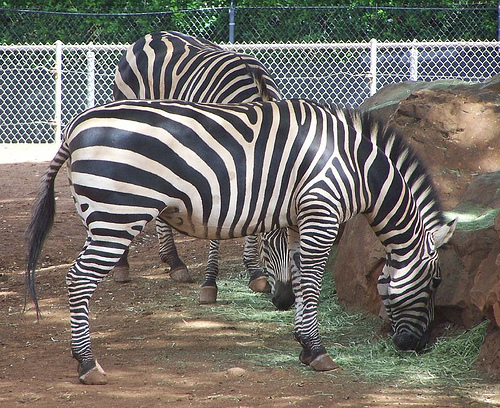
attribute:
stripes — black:
[18, 102, 462, 383]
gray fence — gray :
[2, 43, 498, 155]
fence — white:
[5, 39, 499, 134]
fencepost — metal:
[225, 4, 239, 39]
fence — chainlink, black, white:
[2, 2, 499, 140]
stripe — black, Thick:
[66, 124, 216, 235]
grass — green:
[351, 311, 462, 396]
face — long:
[382, 255, 456, 352]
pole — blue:
[221, 0, 238, 47]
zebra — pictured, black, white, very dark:
[25, 95, 459, 385]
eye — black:
[432, 277, 442, 288]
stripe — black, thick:
[71, 154, 196, 216]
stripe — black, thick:
[357, 132, 374, 209]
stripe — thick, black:
[82, 254, 117, 268]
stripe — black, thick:
[391, 275, 422, 286]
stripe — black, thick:
[321, 112, 338, 162]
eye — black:
[431, 272, 443, 292]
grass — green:
[217, 269, 487, 385]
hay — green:
[101, 241, 493, 401]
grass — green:
[401, 345, 465, 389]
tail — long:
[18, 136, 70, 331]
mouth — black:
[387, 328, 417, 353]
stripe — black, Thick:
[66, 186, 180, 215]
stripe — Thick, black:
[86, 222, 142, 240]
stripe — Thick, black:
[267, 97, 316, 231]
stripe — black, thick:
[355, 115, 378, 209]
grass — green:
[166, 246, 498, 393]